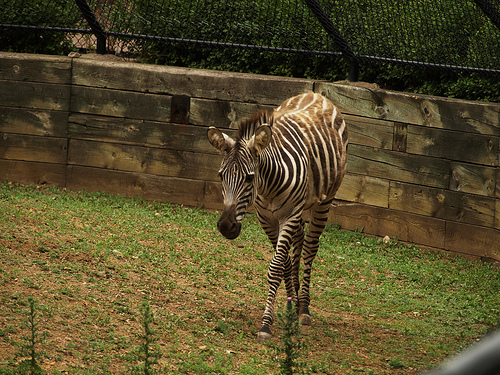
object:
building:
[1, 7, 500, 269]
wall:
[0, 54, 500, 263]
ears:
[206, 123, 235, 150]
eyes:
[216, 168, 229, 183]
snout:
[214, 209, 243, 240]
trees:
[126, 294, 164, 374]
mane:
[231, 105, 278, 157]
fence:
[1, 50, 500, 269]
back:
[266, 91, 332, 139]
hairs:
[234, 109, 279, 144]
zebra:
[204, 88, 352, 338]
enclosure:
[0, 0, 500, 373]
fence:
[0, 2, 500, 99]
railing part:
[423, 330, 500, 373]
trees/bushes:
[0, 0, 500, 105]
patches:
[16, 235, 61, 256]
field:
[0, 178, 500, 374]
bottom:
[0, 183, 500, 374]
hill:
[0, 181, 500, 374]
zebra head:
[205, 118, 275, 243]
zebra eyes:
[241, 171, 259, 185]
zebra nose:
[215, 217, 237, 236]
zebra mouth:
[220, 228, 239, 238]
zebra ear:
[248, 123, 273, 150]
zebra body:
[254, 92, 352, 339]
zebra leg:
[258, 209, 296, 327]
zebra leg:
[296, 204, 326, 312]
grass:
[0, 181, 500, 374]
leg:
[255, 218, 301, 322]